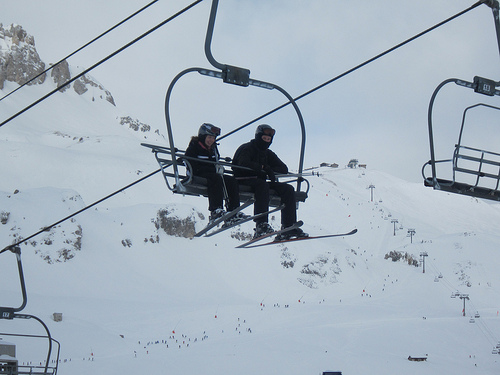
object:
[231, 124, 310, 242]
man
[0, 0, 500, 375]
moutain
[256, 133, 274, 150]
ski mask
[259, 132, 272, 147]
face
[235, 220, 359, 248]
skis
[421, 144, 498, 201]
chair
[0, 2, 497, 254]
suspended cables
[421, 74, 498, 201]
lift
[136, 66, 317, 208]
lifts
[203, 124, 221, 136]
goggles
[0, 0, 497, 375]
snow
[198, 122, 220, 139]
hat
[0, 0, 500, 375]
rocky snow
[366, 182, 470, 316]
power poles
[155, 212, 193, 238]
rock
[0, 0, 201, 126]
lines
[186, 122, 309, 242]
two people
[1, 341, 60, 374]
chair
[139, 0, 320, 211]
ski lift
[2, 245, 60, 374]
lift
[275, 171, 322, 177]
ski poles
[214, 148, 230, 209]
ski poles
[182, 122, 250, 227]
person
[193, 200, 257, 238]
skis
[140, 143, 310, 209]
bench